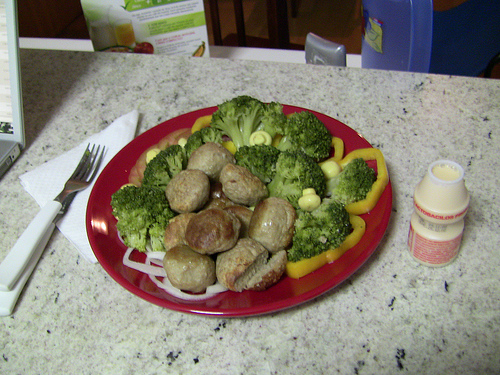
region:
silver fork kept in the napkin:
[24, 140, 105, 245]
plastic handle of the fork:
[5, 189, 70, 310]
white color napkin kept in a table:
[44, 110, 119, 259]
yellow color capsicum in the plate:
[321, 130, 376, 213]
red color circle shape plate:
[87, 93, 388, 314]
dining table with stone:
[70, 52, 472, 371]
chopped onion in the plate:
[124, 248, 225, 310]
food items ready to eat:
[134, 97, 356, 277]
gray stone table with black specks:
[0, 52, 495, 372]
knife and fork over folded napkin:
[1, 96, 141, 312]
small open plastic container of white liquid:
[405, 155, 470, 265]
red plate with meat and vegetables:
[82, 96, 392, 316]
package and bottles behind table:
[80, 0, 430, 70]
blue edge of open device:
[0, 0, 25, 180]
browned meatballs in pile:
[165, 136, 295, 296]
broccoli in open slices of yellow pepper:
[291, 111, 388, 272]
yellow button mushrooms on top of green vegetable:
[295, 147, 340, 208]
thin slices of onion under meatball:
[121, 241, 231, 301]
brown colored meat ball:
[183, 208, 240, 256]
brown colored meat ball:
[216, 243, 283, 292]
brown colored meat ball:
[161, 243, 217, 289]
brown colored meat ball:
[162, 209, 194, 247]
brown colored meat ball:
[168, 170, 208, 210]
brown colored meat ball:
[186, 142, 235, 177]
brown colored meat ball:
[220, 158, 260, 200]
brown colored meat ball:
[251, 193, 291, 253]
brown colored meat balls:
[166, 145, 291, 295]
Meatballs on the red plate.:
[176, 177, 266, 257]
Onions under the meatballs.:
[145, 246, 233, 299]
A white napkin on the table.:
[31, 115, 115, 250]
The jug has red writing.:
[403, 228, 478, 258]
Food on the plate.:
[123, 137, 318, 273]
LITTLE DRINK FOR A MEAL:
[412, 156, 467, 266]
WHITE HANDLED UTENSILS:
[22, 138, 105, 320]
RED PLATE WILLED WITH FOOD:
[89, 103, 388, 320]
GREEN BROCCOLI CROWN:
[114, 184, 174, 251]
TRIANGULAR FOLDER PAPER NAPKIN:
[18, 98, 140, 265]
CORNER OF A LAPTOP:
[0, 0, 30, 190]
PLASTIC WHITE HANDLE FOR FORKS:
[1, 201, 63, 318]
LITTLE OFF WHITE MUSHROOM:
[249, 128, 271, 148]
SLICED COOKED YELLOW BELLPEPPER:
[343, 150, 390, 220]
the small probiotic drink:
[407, 160, 469, 267]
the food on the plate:
[85, 95, 392, 317]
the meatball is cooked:
[248, 195, 295, 251]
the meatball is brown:
[186, 206, 241, 256]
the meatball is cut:
[215, 236, 288, 291]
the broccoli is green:
[111, 185, 175, 252]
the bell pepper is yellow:
[336, 145, 388, 214]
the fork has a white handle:
[0, 141, 104, 291]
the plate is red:
[86, 103, 391, 317]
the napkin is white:
[18, 107, 139, 263]